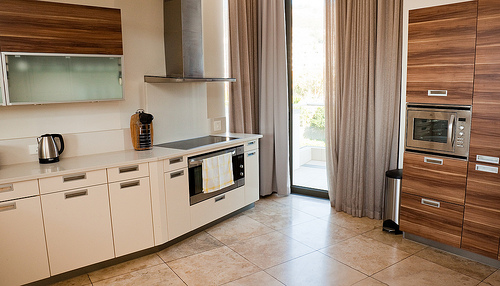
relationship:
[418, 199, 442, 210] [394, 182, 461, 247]
handle in cabinet door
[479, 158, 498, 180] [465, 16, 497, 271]
handle in cabinet door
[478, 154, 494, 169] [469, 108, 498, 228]
handle in cabinet door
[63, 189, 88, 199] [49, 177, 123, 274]
handle in cabinet door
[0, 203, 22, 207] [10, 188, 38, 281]
handle in cabinet door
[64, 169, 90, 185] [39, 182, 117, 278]
handle in cabinet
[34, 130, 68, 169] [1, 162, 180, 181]
kettle on counter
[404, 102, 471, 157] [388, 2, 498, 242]
microwave set in wall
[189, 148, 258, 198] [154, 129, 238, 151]
oven under stove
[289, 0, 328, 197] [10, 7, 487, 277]
door in kitchen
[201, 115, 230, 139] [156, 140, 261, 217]
electrical outlet by stove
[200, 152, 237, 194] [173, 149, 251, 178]
towel on handle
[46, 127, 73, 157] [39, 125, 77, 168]
handle on kettle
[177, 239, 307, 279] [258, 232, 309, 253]
tiles covering floor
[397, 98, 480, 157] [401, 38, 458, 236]
microwave in middle drawers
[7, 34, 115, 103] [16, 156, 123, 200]
cabinets over counter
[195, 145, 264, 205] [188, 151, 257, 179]
towel over handle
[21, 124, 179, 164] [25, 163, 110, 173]
appliances on counter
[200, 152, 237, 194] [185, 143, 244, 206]
towel on door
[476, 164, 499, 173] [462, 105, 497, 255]
handle on cabinet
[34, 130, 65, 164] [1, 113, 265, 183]
pot on top of counter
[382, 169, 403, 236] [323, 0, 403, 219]
can beside curtain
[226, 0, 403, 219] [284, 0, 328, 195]
curtain covering window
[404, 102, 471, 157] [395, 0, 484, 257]
microwave attached to wall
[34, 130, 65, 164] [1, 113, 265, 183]
pot on counter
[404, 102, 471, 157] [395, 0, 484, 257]
microwave in wall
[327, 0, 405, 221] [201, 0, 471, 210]
curtain covering wall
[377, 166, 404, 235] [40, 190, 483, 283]
can on floor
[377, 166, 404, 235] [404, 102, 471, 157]
can next to microwave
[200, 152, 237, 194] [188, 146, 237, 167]
towel on handlebar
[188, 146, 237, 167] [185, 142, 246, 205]
handlebar of oven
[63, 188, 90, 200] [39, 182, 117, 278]
handle on cabinet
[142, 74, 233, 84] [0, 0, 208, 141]
shelf on wall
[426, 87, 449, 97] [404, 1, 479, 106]
handle on cabinet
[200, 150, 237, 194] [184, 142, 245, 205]
cloth hanging from door